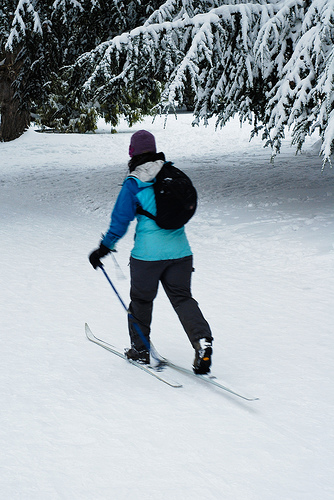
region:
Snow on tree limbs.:
[188, 72, 324, 159]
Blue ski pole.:
[97, 256, 168, 370]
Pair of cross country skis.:
[82, 308, 269, 403]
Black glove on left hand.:
[84, 232, 120, 267]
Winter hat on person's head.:
[124, 124, 162, 158]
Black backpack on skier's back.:
[151, 163, 201, 231]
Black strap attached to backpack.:
[137, 199, 158, 221]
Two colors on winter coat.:
[101, 165, 200, 268]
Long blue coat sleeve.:
[90, 175, 136, 255]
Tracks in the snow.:
[20, 150, 110, 215]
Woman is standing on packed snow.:
[71, 122, 264, 410]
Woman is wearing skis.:
[81, 318, 261, 409]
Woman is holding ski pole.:
[84, 243, 180, 375]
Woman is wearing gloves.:
[85, 240, 119, 271]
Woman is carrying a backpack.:
[123, 157, 202, 234]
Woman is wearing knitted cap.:
[123, 127, 164, 160]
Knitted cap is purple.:
[122, 126, 164, 159]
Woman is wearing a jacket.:
[99, 158, 201, 261]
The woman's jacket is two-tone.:
[84, 162, 209, 267]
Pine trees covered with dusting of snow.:
[2, 2, 333, 164]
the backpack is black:
[131, 161, 222, 242]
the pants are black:
[115, 251, 226, 372]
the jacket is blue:
[98, 164, 199, 279]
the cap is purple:
[122, 128, 154, 158]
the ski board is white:
[82, 304, 275, 467]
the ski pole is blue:
[101, 265, 174, 368]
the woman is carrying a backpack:
[77, 153, 211, 261]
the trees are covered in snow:
[20, 14, 280, 140]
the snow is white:
[28, 307, 104, 431]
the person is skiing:
[53, 113, 279, 430]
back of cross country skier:
[78, 123, 277, 408]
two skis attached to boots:
[77, 317, 268, 416]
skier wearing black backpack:
[148, 160, 199, 242]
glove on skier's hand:
[80, 238, 120, 270]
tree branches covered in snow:
[128, 16, 273, 78]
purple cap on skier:
[122, 125, 164, 161]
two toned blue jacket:
[107, 182, 202, 268]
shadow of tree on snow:
[228, 161, 312, 215]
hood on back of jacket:
[129, 162, 159, 190]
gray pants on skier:
[120, 250, 213, 357]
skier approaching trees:
[78, 81, 274, 403]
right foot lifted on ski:
[113, 258, 265, 407]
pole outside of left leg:
[75, 215, 170, 390]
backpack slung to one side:
[109, 150, 209, 241]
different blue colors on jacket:
[82, 156, 198, 268]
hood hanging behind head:
[105, 133, 175, 194]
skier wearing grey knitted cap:
[120, 122, 166, 181]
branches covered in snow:
[58, 10, 310, 160]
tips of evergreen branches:
[141, 93, 326, 171]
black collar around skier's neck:
[96, 134, 185, 174]